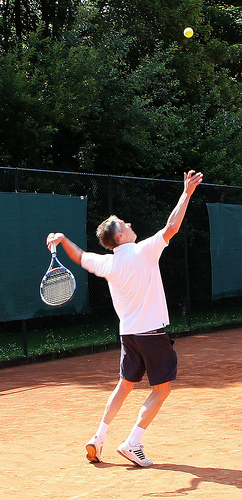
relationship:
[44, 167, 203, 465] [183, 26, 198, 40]
man playing tennis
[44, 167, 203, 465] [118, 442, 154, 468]
man has on tennis shoes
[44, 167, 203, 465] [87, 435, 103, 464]
man has on tennis shoes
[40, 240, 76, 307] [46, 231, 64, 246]
tennis racket in left hand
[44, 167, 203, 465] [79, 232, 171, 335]
man wearing shirt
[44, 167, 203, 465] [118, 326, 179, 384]
man wearing shorts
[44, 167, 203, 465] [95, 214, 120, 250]
man has hair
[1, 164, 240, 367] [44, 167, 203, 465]
fence near man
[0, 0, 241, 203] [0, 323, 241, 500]
trees near tennis court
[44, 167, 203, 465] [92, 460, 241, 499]
man has a shadow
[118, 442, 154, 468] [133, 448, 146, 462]
tennis shoes have lines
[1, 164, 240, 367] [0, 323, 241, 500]
fence near play area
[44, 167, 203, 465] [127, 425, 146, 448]
man wearing socks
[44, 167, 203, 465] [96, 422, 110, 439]
man wearing socks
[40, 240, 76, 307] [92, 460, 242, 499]
tennis racket has a shadow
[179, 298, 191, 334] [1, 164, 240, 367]
weed near fence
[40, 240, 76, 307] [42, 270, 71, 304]
tennis racket has strings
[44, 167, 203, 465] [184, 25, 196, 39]
man serving tennis ball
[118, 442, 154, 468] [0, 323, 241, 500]
tennis shoes are on ground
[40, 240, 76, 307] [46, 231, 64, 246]
tennis racket in man's hand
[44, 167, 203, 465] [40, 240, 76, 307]
man swinging tennis racket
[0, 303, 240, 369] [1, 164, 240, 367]
grass behind fence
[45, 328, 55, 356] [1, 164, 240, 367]
plant behind fence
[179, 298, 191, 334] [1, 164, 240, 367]
plant behind fence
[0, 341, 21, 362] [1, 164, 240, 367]
plant behind fence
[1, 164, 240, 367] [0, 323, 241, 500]
fence near tennis court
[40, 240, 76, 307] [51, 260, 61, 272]
tennis racket has middle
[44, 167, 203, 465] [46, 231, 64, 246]
man has hand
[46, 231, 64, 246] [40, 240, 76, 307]
hand has tennis racket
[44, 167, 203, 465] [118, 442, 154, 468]
man has a foot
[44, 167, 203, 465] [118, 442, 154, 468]
man wearing foot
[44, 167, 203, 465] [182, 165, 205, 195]
man has hand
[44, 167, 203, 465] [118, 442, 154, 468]
man wearing tennis shoes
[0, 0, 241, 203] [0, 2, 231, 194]
trees has leaves